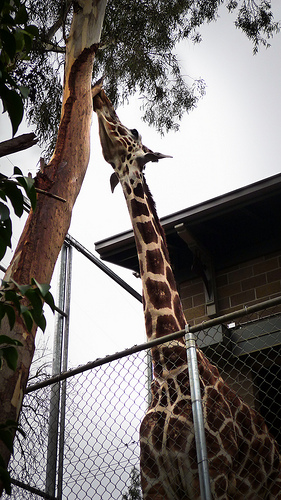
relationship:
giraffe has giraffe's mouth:
[93, 87, 278, 496] [92, 87, 116, 113]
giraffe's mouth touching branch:
[92, 87, 116, 113] [86, 79, 108, 98]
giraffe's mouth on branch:
[92, 87, 116, 113] [88, 77, 107, 97]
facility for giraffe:
[97, 166, 277, 473] [93, 89, 281, 500]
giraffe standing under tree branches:
[93, 89, 281, 500] [5, 18, 179, 432]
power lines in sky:
[71, 451, 132, 476] [104, 309, 106, 310]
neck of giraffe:
[117, 173, 187, 322] [93, 87, 278, 496]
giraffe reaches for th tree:
[93, 87, 278, 496] [0, 0, 279, 496]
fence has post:
[1, 296, 281, 497] [182, 317, 221, 498]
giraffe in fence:
[93, 89, 281, 500] [6, 293, 279, 498]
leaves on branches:
[0, 167, 63, 371] [2, 169, 69, 208]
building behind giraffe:
[141, 245, 271, 327] [93, 87, 278, 496]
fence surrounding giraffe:
[1, 296, 281, 497] [93, 87, 278, 496]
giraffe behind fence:
[93, 87, 278, 496] [1, 296, 281, 497]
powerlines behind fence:
[0, 439, 140, 498] [11, 360, 260, 497]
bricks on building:
[176, 264, 271, 311] [186, 167, 271, 402]